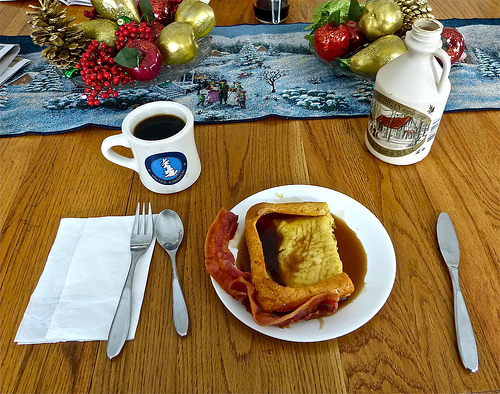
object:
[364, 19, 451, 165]
bottle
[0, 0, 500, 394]
table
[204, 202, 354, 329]
bacon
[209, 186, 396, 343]
plate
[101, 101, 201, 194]
cup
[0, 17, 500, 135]
table runner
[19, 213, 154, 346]
napkin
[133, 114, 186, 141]
coffee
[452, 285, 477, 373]
handle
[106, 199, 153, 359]
fork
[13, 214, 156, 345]
napkin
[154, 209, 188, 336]
spoon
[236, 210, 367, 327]
syrup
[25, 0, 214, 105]
centerpiece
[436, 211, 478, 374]
knife